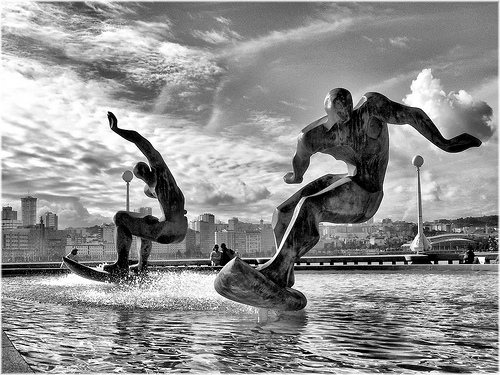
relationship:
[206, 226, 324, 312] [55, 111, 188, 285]
sculpture of statue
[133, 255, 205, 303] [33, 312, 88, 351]
waves are on water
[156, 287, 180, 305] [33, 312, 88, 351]
droplets of water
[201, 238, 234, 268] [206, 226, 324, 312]
couple looking at sculpture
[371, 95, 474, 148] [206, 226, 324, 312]
arm of sculpture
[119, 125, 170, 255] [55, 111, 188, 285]
statue of statue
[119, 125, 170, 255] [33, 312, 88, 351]
statue in water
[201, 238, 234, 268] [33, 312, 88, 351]
couple near water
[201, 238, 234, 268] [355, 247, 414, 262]
couple on water bridge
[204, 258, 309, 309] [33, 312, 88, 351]
surfboard on water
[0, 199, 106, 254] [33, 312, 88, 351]
city behind water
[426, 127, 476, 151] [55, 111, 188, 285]
hand of statue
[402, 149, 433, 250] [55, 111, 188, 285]
structure shaped like statue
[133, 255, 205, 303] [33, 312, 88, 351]
waves on top of water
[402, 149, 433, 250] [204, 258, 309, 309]
structure on surfboard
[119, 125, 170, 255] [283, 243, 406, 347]
statue in pool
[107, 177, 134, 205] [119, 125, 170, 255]
poles are behind statue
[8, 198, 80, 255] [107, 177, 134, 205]
building left of poles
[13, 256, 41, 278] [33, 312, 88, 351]
railing along water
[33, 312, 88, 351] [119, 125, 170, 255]
water falling from statue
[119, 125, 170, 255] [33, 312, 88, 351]
statue on water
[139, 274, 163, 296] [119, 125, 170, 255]
spray from statue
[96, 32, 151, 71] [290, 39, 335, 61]
clouds are inside sky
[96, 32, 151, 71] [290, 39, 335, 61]
clouds are on sky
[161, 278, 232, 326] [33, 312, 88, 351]
reflection on water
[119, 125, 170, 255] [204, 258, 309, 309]
statue on top of surfboard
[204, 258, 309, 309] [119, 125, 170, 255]
surfboard with statue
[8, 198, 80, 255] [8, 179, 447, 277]
building in background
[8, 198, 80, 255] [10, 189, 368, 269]
building in background